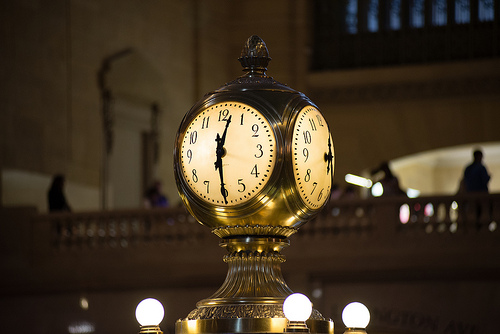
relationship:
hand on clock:
[213, 113, 231, 171] [182, 101, 277, 208]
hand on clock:
[213, 113, 230, 200] [182, 101, 277, 208]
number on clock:
[250, 120, 260, 138] [182, 101, 277, 208]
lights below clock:
[104, 279, 372, 332] [182, 101, 277, 208]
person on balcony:
[451, 142, 491, 217] [13, 200, 493, 280]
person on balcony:
[364, 158, 411, 201] [13, 200, 493, 280]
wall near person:
[9, 7, 144, 125] [40, 169, 75, 211]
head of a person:
[462, 142, 484, 169] [451, 142, 491, 217]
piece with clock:
[152, 27, 360, 243] [182, 101, 277, 208]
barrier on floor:
[40, 190, 497, 277] [12, 253, 492, 289]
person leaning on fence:
[451, 142, 491, 217] [4, 190, 498, 254]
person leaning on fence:
[40, 169, 75, 211] [4, 190, 498, 254]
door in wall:
[104, 119, 154, 236] [9, 7, 144, 125]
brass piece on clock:
[237, 32, 271, 74] [173, 34, 335, 331]